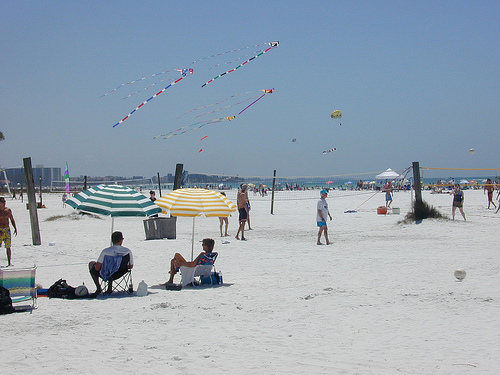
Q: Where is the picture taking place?
A: The beach.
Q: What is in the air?
A: Kites.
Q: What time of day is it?
A: Day time.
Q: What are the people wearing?
A: Shorts and swimsuits.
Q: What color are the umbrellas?
A: Blue, yellow and white.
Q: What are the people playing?
A: Volleyball.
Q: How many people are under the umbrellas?
A: Two.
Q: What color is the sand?
A: White.